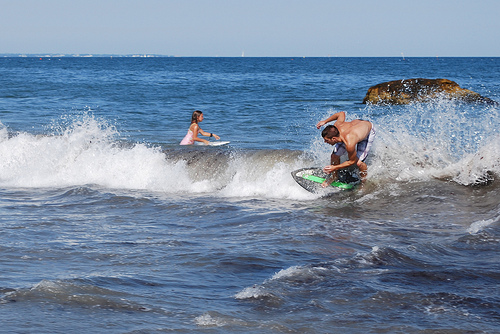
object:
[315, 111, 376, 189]
man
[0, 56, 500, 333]
water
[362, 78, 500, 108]
rock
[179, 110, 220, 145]
girl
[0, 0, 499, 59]
sky